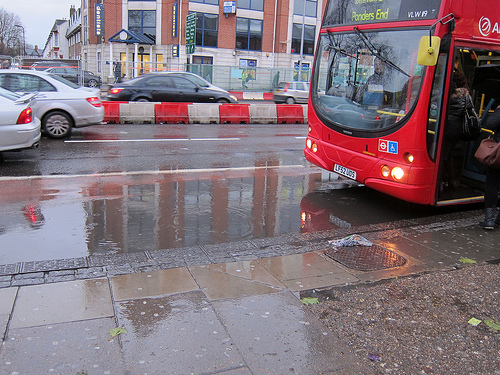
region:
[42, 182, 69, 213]
wet cement on road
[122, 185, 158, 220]
wet cement on road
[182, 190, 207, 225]
wet cement on road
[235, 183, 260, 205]
wet cement on road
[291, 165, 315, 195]
wet cement on road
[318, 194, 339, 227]
wet cement on road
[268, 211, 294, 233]
wet cement on road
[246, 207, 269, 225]
wet cement on road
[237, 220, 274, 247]
wet cement on road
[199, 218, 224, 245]
wet cement on road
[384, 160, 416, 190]
a left front headlight on a bus.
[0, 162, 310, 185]
a dividing line on a street.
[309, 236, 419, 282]
a man hole cover.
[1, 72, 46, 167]
a silver car on a street.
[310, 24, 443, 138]
a windshield on a red city bus.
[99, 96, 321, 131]
red and gray road divider.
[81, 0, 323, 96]
a multi story building.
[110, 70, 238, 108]
a black compact car.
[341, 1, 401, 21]
a marque on a city bus.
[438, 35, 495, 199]
a loading door on a bus.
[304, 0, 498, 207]
Red mass transit bus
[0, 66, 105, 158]
Two silver cars on the road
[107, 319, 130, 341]
Green leaf on the ground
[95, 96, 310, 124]
Red and white traffic barriers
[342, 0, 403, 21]
LED bus route sign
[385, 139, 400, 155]
Blue handicap sticker on a bus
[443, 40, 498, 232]
People boarding a bus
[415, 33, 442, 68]
Yellow back of a side view mirror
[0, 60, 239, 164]
Four vehicles driving on a wet road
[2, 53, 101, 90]
Vehicles parked in a building lot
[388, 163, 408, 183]
Headlight on red bus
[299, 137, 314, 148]
Headlight on red bus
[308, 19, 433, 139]
Front windshield of red bus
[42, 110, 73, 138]
Rear wheel of car in traffic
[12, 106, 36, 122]
Tail light of car in traffic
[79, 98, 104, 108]
tail light of car in traffic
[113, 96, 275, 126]
Red and white traffic barricade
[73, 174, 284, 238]
Reflection of building on wet street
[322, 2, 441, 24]
Designation sign on red bus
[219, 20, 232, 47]
Part of red brick building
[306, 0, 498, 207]
a red bus with door open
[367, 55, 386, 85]
the bus driver through the windshield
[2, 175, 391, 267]
giant puddle in front of the bus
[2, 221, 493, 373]
the concrete sidewalk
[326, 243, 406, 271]
a manhole cover on the sidewalk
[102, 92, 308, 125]
red and white temporary barriers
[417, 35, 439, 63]
yellow mirror on the bus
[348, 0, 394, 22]
digital route sign on the bus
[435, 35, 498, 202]
open front passenger door on bus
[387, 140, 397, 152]
blue handicap sticker on front of bus